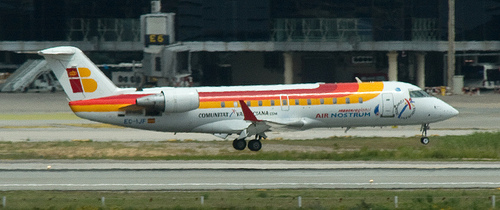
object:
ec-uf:
[123, 118, 145, 124]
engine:
[135, 88, 200, 113]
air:
[316, 113, 329, 118]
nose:
[427, 99, 459, 123]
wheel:
[420, 137, 430, 145]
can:
[440, 85, 446, 96]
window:
[409, 90, 431, 98]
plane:
[36, 46, 459, 152]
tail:
[37, 46, 116, 102]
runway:
[0, 159, 500, 192]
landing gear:
[232, 138, 262, 151]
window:
[345, 97, 350, 103]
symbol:
[66, 67, 98, 93]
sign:
[140, 13, 175, 79]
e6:
[150, 34, 164, 42]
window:
[295, 99, 300, 105]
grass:
[0, 131, 499, 162]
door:
[382, 93, 394, 117]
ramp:
[0, 59, 51, 93]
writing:
[331, 112, 371, 118]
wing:
[192, 117, 323, 140]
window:
[221, 101, 225, 107]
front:
[394, 81, 460, 125]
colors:
[66, 66, 384, 112]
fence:
[0, 196, 500, 210]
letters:
[145, 34, 170, 45]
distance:
[12, 8, 500, 101]